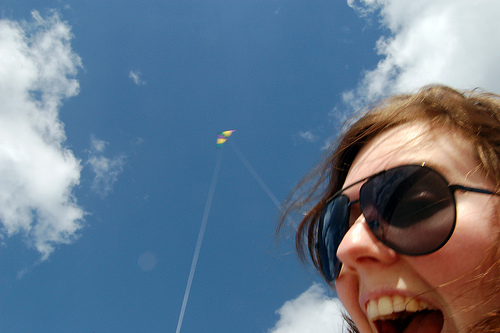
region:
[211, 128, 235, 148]
a kite flying in the air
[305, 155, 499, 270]
the sunglasses on the woman's face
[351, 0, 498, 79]
a white cloud in the sky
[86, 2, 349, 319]
a big section of the blue sky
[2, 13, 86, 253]
another white cloud in the sky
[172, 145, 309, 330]
some strings attached to the kite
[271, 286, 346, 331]
a tiny little white cloud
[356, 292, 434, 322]
the woman's teeth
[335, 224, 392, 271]
the woman's partially covered nose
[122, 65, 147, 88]
a tiny piece of cloud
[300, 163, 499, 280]
Woman wearing glasses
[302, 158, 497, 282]
Woman is wearing glasses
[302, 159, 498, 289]
Woman wearing black glasses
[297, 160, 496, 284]
Woman is wearing black glasses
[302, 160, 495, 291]
Woman wearing sunglasses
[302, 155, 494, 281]
Woman is wearing sunglasses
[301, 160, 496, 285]
Woman wearing black sunglasses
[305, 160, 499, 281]
Woman is wearing black sunglasses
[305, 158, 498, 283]
Woman wearing black aviator sunglasses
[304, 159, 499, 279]
Woman is wearing black aviator sunglasses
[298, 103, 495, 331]
girl on right watching kite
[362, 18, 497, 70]
white clouds in sky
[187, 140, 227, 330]
long string on kite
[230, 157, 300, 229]
long string on kite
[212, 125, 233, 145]
yellow kite in air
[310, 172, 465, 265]
aviator glasses on girl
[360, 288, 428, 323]
white teeth on girl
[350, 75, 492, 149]
brown hair on girl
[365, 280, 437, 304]
red lips on girl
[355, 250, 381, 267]
left nostril of girl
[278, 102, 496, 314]
the head of a woman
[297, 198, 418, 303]
the nose of a woman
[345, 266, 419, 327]
the teeth of a woman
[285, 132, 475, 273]
a woman wearing sunglasses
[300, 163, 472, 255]
the eye of a woman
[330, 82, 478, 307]
the face of a woman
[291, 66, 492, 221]
the hair of a woman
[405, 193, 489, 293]
the cheek of a woman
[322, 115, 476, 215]
the forehead of a woman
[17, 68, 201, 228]
clouds in a sky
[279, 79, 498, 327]
beautiful smile of a woman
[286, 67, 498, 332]
woman wearing sun glasses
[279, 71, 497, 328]
person wearing a sun glasses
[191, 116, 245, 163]
kite in the sky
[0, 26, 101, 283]
clouds in the sky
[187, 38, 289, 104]
a clear blue sky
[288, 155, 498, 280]
a black sun glasses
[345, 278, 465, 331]
smile of a woman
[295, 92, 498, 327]
head of a beautiful woman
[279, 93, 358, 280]
hair of a woman